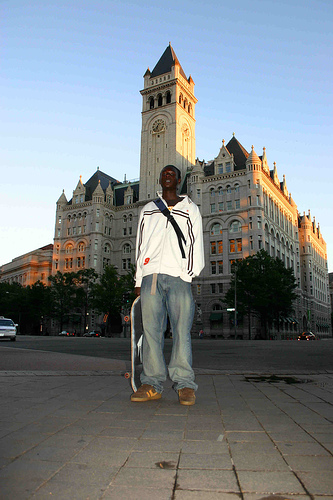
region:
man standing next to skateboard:
[120, 153, 211, 416]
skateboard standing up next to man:
[117, 290, 149, 398]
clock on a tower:
[146, 112, 167, 136]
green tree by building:
[230, 242, 297, 346]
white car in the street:
[1, 304, 21, 344]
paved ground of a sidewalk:
[22, 375, 131, 472]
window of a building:
[226, 233, 242, 256]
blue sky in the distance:
[20, 24, 117, 109]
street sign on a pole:
[222, 301, 235, 317]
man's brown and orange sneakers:
[128, 377, 202, 406]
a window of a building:
[227, 238, 238, 252]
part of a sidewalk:
[0, 359, 330, 498]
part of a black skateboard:
[122, 296, 145, 394]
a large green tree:
[228, 247, 300, 346]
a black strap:
[153, 197, 189, 251]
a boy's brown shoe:
[177, 388, 198, 407]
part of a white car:
[0, 314, 20, 341]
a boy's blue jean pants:
[138, 277, 200, 392]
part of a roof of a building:
[227, 133, 249, 167]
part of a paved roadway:
[189, 330, 329, 371]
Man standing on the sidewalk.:
[126, 150, 208, 431]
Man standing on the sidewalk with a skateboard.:
[125, 160, 213, 407]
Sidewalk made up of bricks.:
[72, 411, 258, 488]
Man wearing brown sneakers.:
[130, 371, 199, 404]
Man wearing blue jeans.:
[136, 268, 196, 391]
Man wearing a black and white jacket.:
[127, 190, 205, 291]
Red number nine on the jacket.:
[138, 252, 154, 271]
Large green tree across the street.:
[223, 244, 297, 341]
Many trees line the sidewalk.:
[7, 262, 130, 343]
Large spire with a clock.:
[139, 65, 182, 166]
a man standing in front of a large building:
[123, 155, 204, 420]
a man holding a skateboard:
[122, 162, 207, 412]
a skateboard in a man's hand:
[125, 286, 148, 396]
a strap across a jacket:
[149, 190, 199, 265]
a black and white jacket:
[118, 191, 212, 288]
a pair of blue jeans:
[133, 271, 197, 396]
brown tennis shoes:
[121, 382, 202, 405]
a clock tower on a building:
[137, 38, 197, 168]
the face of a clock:
[146, 115, 170, 134]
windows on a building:
[205, 182, 246, 272]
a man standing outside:
[108, 156, 312, 395]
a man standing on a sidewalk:
[117, 171, 202, 363]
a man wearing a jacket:
[114, 158, 219, 311]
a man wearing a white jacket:
[119, 153, 214, 292]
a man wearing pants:
[107, 169, 206, 462]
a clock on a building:
[139, 98, 185, 163]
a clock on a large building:
[136, 79, 184, 145]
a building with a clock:
[138, 87, 176, 165]